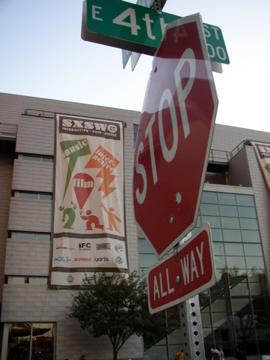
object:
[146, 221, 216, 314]
sign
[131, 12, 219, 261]
sign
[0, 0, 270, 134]
sky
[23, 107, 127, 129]
rail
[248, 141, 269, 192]
poster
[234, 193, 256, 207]
window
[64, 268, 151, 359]
tree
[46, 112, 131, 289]
ad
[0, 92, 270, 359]
building